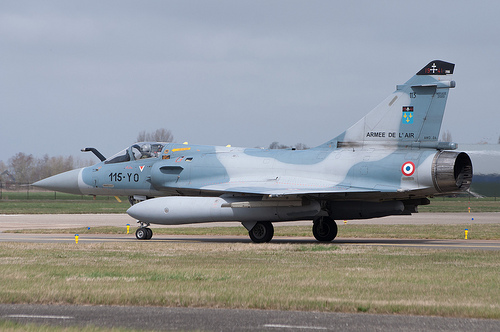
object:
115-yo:
[108, 172, 140, 182]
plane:
[31, 58, 471, 241]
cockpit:
[104, 142, 164, 166]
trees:
[0, 120, 497, 200]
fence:
[0, 170, 500, 207]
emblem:
[401, 161, 416, 176]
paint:
[401, 161, 416, 176]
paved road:
[0, 300, 500, 330]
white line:
[258, 321, 325, 330]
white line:
[3, 312, 73, 320]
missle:
[123, 192, 329, 227]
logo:
[400, 160, 415, 178]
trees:
[0, 152, 98, 190]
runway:
[0, 300, 498, 330]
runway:
[0, 212, 500, 228]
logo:
[402, 105, 415, 124]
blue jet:
[18, 57, 485, 245]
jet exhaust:
[432, 150, 472, 196]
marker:
[463, 228, 470, 241]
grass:
[1, 244, 498, 314]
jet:
[31, 59, 483, 242]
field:
[0, 190, 500, 313]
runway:
[0, 227, 499, 255]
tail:
[316, 60, 457, 149]